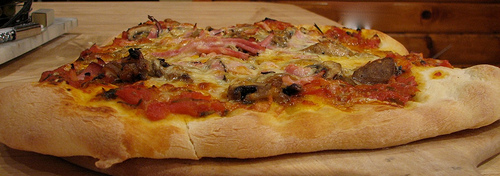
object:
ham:
[198, 30, 273, 60]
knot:
[419, 8, 435, 19]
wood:
[358, 0, 499, 36]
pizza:
[4, 15, 496, 167]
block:
[0, 13, 499, 176]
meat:
[352, 56, 396, 85]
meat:
[303, 39, 351, 56]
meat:
[245, 74, 283, 102]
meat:
[125, 20, 156, 40]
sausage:
[351, 56, 398, 83]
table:
[5, 1, 350, 82]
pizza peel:
[2, 65, 500, 175]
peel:
[59, 128, 499, 173]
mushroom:
[349, 53, 400, 85]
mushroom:
[237, 73, 289, 105]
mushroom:
[316, 60, 343, 81]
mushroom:
[126, 22, 162, 40]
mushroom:
[265, 26, 297, 48]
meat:
[109, 44, 153, 83]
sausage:
[255, 68, 292, 106]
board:
[0, 12, 79, 67]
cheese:
[37, 19, 428, 111]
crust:
[0, 64, 499, 169]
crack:
[175, 115, 209, 167]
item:
[1, 10, 76, 55]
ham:
[233, 43, 266, 55]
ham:
[209, 46, 249, 60]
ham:
[192, 31, 244, 45]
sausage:
[115, 46, 158, 75]